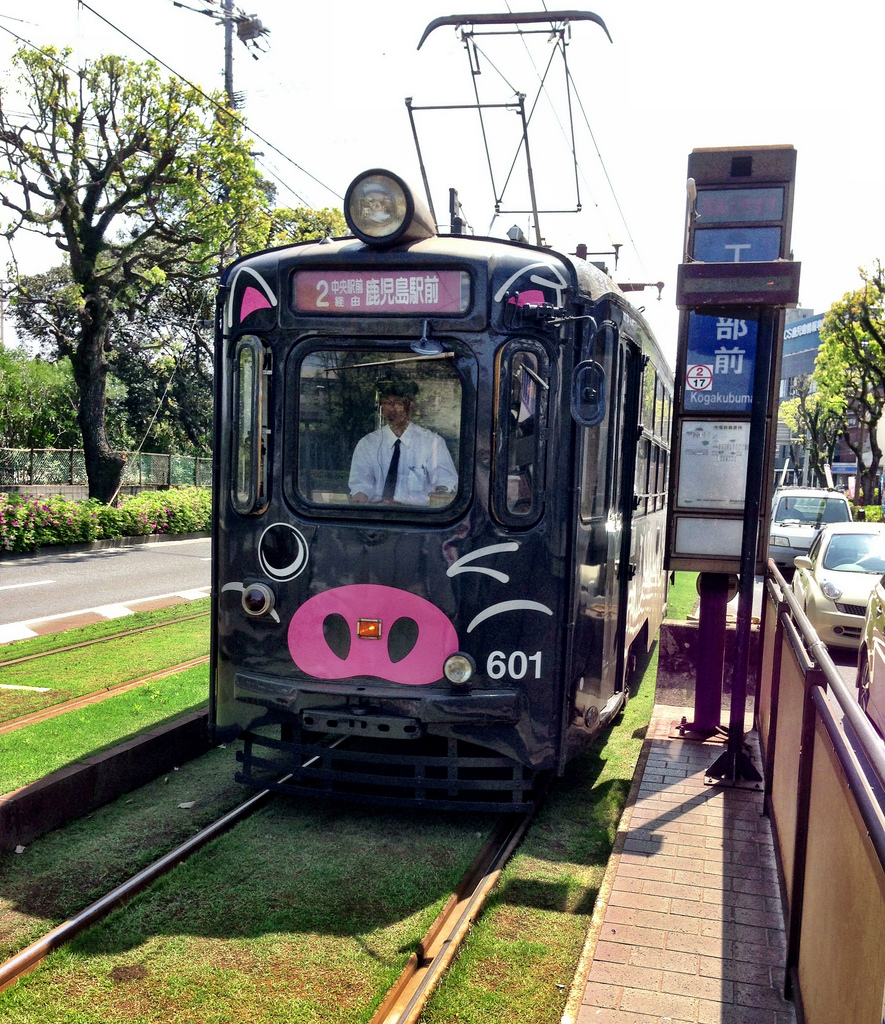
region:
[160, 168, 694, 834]
THIS IS A TRAIN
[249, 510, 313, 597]
THIS IS AN EYE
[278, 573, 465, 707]
THIS IS A PIGS NOSE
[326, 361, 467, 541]
THIS MAN IS IN THE TRAIN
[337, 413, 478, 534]
THIS IS A WHITE SHIRT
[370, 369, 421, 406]
THIS IS A BLACK HAT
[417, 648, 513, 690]
THIS IS A LIGHT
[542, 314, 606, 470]
THIS IS A MIRROR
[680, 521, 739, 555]
sign on the pole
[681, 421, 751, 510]
sign on the pole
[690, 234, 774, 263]
sign on the pole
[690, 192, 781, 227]
sign on the pole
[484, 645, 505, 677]
number on the train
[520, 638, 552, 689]
number on the train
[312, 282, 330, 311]
number on the train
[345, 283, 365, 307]
number on the train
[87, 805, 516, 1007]
long section of train tracks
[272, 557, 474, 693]
pink logo on black train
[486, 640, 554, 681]
white words on the train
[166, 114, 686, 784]
shiny black train on track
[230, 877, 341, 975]
sparse grass in middle of track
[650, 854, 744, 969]
tiles on the platform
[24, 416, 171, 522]
fence on the side of flowers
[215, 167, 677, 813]
black train car on the train tracks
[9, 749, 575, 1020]
train tracks the train is on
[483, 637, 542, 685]
white numbers on the black train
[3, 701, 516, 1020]
shadow of the train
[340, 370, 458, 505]
man driving the train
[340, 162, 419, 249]
light on top of the train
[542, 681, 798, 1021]
platform next to the train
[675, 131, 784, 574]
sign next to train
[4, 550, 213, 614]
The black paved road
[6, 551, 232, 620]
A black paved road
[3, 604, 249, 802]
The grassy area to the left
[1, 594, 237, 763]
A grassy area to the left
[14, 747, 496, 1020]
The grassy area in front the train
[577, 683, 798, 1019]
The brick platform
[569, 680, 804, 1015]
A brick platform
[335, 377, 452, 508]
a man that is driving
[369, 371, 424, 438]
the head of a man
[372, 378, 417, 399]
the hat of a man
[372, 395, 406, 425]
the face of a man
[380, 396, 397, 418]
the glasses of a man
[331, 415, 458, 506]
a shirt of a man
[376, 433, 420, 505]
the tie of a man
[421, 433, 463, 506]
the right arm of a man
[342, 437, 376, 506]
the left arm of a man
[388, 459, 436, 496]
the pocket of a man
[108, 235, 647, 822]
front of the train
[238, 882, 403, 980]
shadow on the ground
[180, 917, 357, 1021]
green and brown ground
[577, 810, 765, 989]
bricks next to grass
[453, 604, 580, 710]
number on the train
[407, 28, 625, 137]
wires above the ground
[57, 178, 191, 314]
branches on the tree